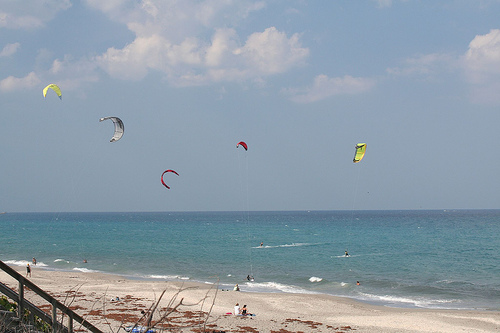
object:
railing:
[0, 259, 105, 333]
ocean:
[0, 209, 500, 314]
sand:
[0, 261, 500, 333]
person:
[233, 283, 240, 292]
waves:
[244, 281, 325, 296]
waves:
[358, 291, 490, 311]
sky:
[0, 0, 500, 213]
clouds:
[97, 20, 320, 88]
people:
[239, 304, 256, 316]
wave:
[308, 276, 323, 283]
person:
[246, 274, 251, 281]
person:
[356, 281, 359, 285]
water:
[0, 209, 500, 311]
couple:
[239, 304, 253, 316]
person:
[32, 256, 37, 265]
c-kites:
[352, 142, 368, 164]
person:
[344, 250, 350, 257]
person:
[26, 263, 33, 277]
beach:
[0, 261, 500, 333]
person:
[233, 302, 243, 316]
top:
[233, 306, 243, 316]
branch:
[129, 301, 157, 332]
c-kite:
[41, 82, 63, 102]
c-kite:
[97, 115, 126, 144]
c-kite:
[159, 168, 180, 190]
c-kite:
[235, 140, 249, 152]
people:
[260, 241, 265, 248]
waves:
[250, 242, 311, 249]